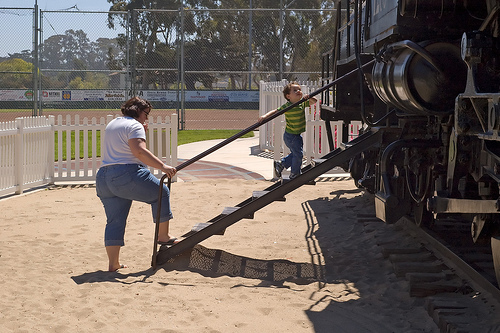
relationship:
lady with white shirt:
[94, 94, 177, 273] [93, 111, 161, 171]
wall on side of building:
[168, 20, 231, 90] [134, 14, 327, 105]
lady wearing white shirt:
[94, 94, 177, 273] [103, 111, 150, 171]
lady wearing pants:
[94, 94, 177, 273] [94, 163, 172, 248]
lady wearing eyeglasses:
[94, 94, 177, 273] [135, 109, 153, 119]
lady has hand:
[94, 94, 177, 273] [157, 159, 177, 186]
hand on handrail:
[157, 159, 177, 186] [154, 41, 408, 242]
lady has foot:
[94, 94, 177, 273] [156, 230, 182, 251]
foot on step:
[156, 230, 182, 251] [154, 232, 190, 267]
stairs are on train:
[152, 126, 388, 266] [150, 1, 500, 300]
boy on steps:
[257, 82, 319, 180] [154, 118, 406, 262]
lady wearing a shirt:
[85, 80, 173, 276] [101, 109, 141, 165]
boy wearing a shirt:
[257, 82, 319, 180] [281, 105, 304, 133]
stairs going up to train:
[178, 150, 345, 254] [319, 18, 484, 248]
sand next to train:
[25, 275, 74, 323] [328, 30, 481, 202]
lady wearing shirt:
[94, 94, 177, 273] [97, 116, 147, 161]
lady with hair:
[94, 94, 177, 273] [117, 94, 156, 120]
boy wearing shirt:
[257, 82, 319, 180] [278, 103, 299, 133]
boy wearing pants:
[257, 82, 319, 180] [267, 124, 307, 180]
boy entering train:
[279, 75, 309, 181] [328, 10, 458, 200]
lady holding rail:
[94, 94, 177, 273] [178, 146, 198, 171]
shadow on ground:
[211, 247, 306, 289] [54, 282, 122, 326]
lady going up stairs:
[94, 94, 177, 273] [166, 148, 333, 253]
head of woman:
[109, 92, 180, 123] [84, 81, 168, 257]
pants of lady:
[90, 160, 173, 262] [94, 94, 177, 273]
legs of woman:
[95, 161, 172, 246] [73, 81, 171, 264]